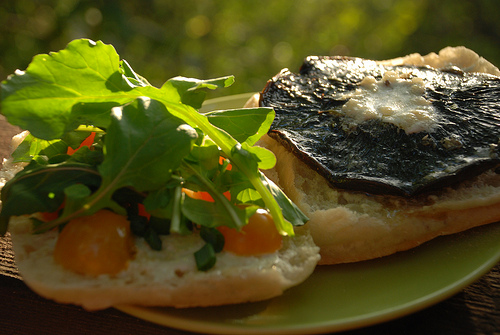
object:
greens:
[96, 68, 158, 129]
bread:
[144, 244, 174, 283]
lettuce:
[1, 38, 308, 257]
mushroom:
[281, 61, 482, 184]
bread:
[325, 196, 357, 229]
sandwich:
[16, 39, 476, 313]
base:
[360, 73, 416, 124]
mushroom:
[267, 70, 319, 145]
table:
[446, 297, 476, 325]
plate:
[10, 23, 484, 321]